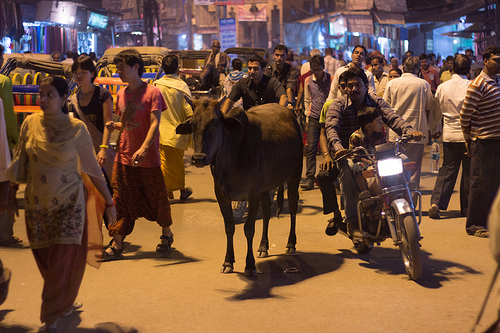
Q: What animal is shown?
A: A bull.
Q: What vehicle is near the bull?
A: A motorcycle.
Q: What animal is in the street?
A: A cow.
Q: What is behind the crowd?
A: Buildings.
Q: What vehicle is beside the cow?
A: Motorcycle.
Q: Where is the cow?
A: On the street.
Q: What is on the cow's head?
A: Horns.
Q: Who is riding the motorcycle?
A: Two men and a boy.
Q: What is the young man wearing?
A: Red t shirt.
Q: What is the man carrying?
A: Water bottle.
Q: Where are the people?
A: In the street.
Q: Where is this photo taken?
A: On a public road.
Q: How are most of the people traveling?
A: Most of them are traveling by foot.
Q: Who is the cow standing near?
A: Men and women.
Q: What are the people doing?
A: Enjoying a night on the street.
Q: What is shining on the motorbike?
A: A light.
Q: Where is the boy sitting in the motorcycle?
A: Front.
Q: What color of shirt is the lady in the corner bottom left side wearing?
A: White.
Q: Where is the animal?
A: In the middle.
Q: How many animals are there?
A: 1.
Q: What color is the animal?
A: Brown.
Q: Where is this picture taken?
A: On the sidewalk.